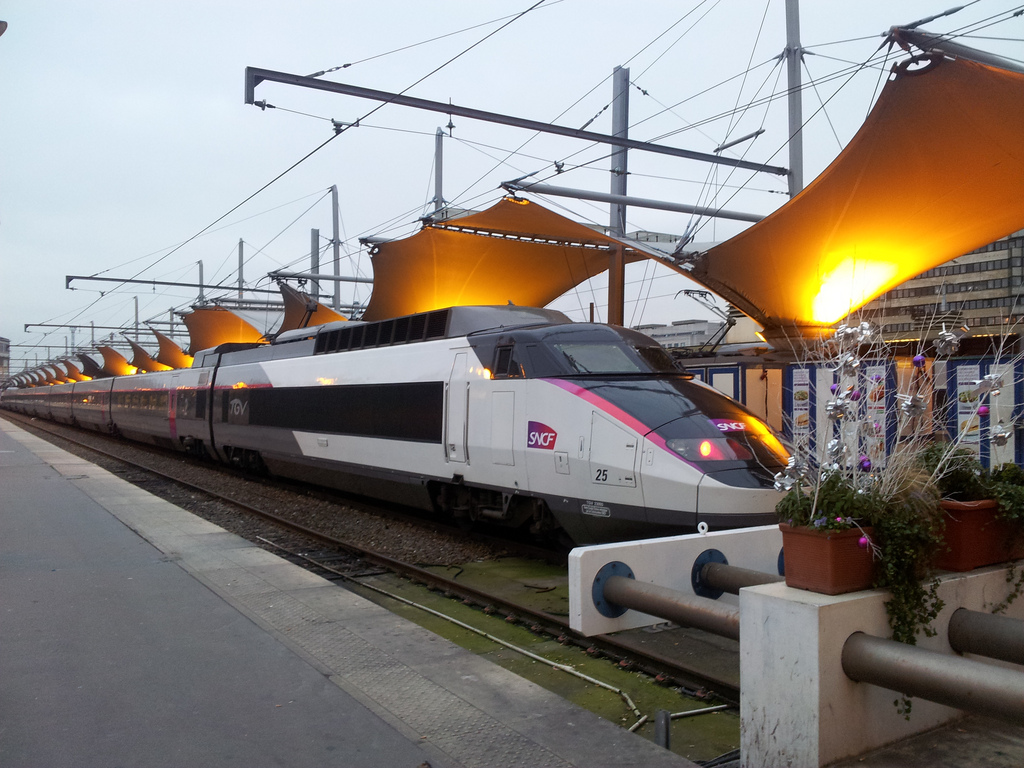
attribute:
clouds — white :
[170, 70, 283, 170]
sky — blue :
[23, 11, 851, 357]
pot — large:
[786, 519, 864, 593]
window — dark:
[479, 311, 678, 385]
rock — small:
[269, 501, 337, 534]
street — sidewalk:
[8, 417, 609, 765]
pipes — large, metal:
[840, 616, 1022, 718]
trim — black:
[516, 318, 772, 498]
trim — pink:
[564, 368, 709, 479]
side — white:
[265, 324, 553, 474]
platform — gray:
[8, 415, 464, 761]